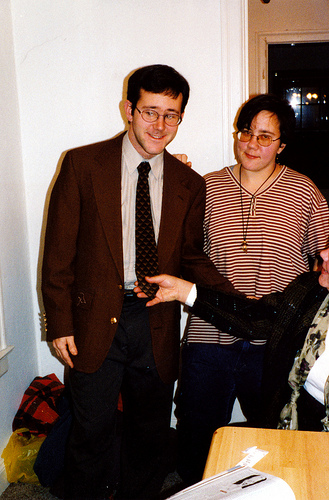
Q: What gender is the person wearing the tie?
A: Male.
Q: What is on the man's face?
A: Glasses.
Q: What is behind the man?
A: Wall.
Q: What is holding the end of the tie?
A: Hand.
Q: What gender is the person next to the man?
A: Female.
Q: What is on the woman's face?
A: Glasses.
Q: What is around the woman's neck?
A: Necklace.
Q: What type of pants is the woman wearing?
A: Jeans.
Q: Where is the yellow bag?
A: Corner behind the man.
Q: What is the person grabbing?
A: A tie.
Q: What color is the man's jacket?
A: Brown.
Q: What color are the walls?
A: White.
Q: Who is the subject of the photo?
A: The couple.